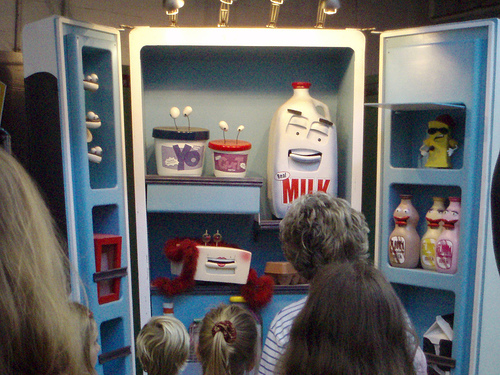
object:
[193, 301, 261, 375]
girl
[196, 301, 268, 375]
hair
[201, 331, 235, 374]
ponytail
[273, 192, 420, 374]
girl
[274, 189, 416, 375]
hair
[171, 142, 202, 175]
word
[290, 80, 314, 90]
top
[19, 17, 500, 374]
refrigerator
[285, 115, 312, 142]
eye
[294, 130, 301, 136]
pupil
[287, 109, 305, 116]
eyebrow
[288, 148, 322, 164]
mouth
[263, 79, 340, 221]
milk carton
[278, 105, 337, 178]
face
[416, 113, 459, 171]
mustard bottle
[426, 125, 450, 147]
face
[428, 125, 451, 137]
sunglasses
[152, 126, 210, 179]
yogurt container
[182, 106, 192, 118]
eye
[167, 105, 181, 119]
eye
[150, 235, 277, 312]
scarf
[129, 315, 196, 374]
boy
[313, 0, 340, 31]
light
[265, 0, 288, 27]
light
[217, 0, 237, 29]
light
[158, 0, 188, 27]
light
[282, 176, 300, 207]
letter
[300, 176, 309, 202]
letter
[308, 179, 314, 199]
letter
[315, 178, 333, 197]
letter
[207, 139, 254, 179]
container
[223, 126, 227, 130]
eyeball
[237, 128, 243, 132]
eyeball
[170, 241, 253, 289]
toaster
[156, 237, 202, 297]
arm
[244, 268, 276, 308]
arm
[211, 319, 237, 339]
holder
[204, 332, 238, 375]
hair scrunchie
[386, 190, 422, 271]
bottle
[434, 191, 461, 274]
bottle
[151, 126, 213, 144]
lid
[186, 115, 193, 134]
stick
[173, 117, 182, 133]
stick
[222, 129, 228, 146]
stick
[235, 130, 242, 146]
stick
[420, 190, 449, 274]
bottle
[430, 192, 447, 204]
lid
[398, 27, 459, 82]
light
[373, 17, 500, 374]
door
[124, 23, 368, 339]
edge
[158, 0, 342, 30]
row of lights